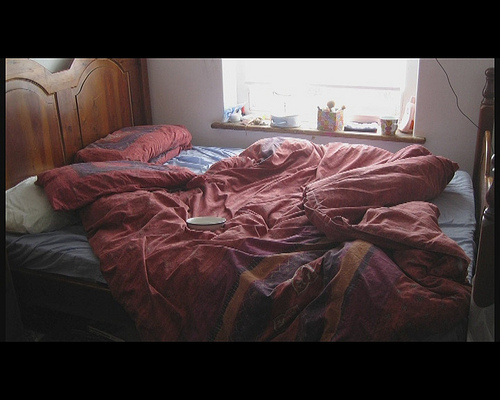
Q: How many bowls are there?
A: One.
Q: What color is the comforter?
A: It is red.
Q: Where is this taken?
A: In a bedroom.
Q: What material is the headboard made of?
A: It is wood.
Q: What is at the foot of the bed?
A: Wooden frame.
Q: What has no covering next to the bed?
A: Window.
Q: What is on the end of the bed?
A: Footboard.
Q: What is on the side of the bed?
A: Window.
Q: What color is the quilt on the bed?
A: Burgundy.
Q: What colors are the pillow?
A: Pink and purple.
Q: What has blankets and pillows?
A: Bed.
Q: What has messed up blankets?
A: Bed.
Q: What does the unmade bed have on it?
A: Bowl.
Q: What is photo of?
A: Bed and blankets.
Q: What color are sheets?
A: Blue.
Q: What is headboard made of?
A: Wooden.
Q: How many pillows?
A: 3.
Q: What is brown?
A: Headboard.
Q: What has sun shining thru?
A: Large window.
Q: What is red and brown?
A: Bedspread.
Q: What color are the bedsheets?
A: Red.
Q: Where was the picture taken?
A: My bedroom.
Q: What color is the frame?
A: Brown.